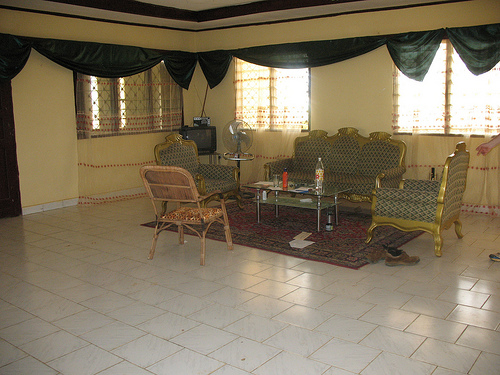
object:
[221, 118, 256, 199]
fan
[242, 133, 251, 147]
blades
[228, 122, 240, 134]
blades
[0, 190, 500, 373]
floor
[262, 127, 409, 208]
couch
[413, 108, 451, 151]
ground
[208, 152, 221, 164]
stand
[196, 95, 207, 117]
antennas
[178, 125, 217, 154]
rocks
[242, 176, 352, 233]
coffee table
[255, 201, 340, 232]
legs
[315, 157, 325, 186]
bottle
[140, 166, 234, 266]
chair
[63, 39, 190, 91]
black drapes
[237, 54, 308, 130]
window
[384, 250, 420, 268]
shoe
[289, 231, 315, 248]
white papers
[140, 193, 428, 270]
rug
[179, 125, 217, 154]
television